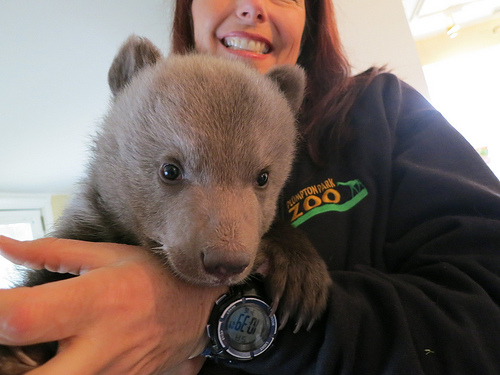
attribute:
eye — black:
[159, 161, 182, 186]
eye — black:
[253, 165, 269, 188]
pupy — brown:
[128, 127, 283, 291]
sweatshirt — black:
[199, 67, 499, 374]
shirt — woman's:
[273, 66, 496, 373]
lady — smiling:
[1, 2, 497, 373]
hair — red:
[169, 0, 394, 175]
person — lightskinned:
[3, 0, 497, 373]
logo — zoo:
[285, 174, 368, 231]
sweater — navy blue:
[273, 71, 498, 371]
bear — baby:
[20, 32, 309, 373]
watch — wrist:
[201, 286, 293, 374]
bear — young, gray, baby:
[1, 35, 331, 373]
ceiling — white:
[28, 27, 113, 127]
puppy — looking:
[23, 38, 334, 328]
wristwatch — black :
[201, 276, 283, 371]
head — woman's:
[171, 0, 354, 110]